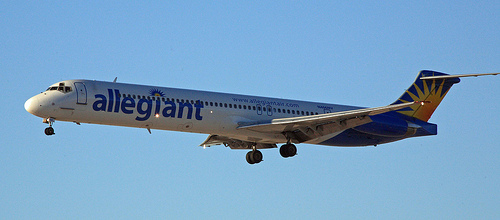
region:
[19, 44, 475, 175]
airplane in the sky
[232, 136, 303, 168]
two wheels are down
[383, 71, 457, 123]
drawing of a sun on the tail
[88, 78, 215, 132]
large blue logo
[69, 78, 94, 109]
white door on the front of the plane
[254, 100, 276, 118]
two emergency exit doors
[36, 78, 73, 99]
windows of the cockpit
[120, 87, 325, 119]
long row of tiny windows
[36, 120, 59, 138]
front wheel is down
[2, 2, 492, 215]
clear blue sky with no clouds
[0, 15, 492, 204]
plane in the air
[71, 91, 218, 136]
words on side of plane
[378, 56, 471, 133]
tail of the plane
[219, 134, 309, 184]
wheels on the plane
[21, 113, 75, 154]
front wheel of the plane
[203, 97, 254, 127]
windows on side of plane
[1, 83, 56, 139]
nose of the plane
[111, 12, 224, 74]
blue sky behind plane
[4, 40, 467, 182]
one plane in the air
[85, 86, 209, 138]
word on side of plane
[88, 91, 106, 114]
blue letter A print on a plane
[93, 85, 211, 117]
blue print on a plane reading allegiant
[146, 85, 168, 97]
blue and yellow sun lego on a gray plane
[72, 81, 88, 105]
door on the gray plane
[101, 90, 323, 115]
row of windows on a plane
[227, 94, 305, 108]
website address printed on a plane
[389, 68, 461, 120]
plane tail with a sun design on it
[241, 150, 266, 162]
black plane wheels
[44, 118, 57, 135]
black front plane wheel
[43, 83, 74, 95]
cockpit window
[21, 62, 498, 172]
a plane in the sky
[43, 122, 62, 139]
the wheel of a plane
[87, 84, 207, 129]
blue writing on the plane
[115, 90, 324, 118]
a row of windows on the plane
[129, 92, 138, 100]
a window on the plane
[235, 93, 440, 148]
the wing of a plane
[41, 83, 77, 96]
the windshield of a plane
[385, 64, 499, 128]
the tail of a plane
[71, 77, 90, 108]
the door of a plane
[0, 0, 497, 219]
a clear blue sky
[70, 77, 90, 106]
a door on the plane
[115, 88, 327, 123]
a row of windows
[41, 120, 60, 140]
a wheel on the plane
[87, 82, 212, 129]
writing on the plane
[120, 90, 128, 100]
a window on the plane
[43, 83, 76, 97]
a windshield on the plane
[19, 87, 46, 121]
the nose of the plane